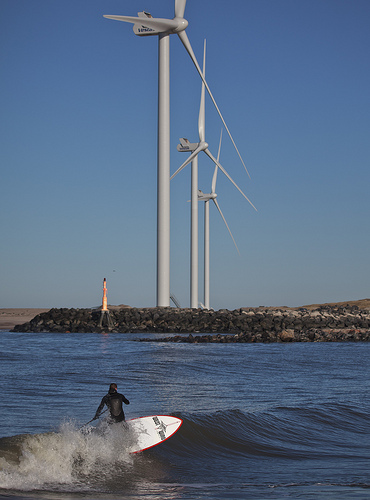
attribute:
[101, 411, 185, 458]
board — wide, white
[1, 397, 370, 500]
wave — foamy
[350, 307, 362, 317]
rock — large, black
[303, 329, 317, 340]
rock — large, black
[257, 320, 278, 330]
rock — large, black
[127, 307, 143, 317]
rock — large, black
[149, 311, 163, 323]
rock — large, black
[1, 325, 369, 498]
water — splashing, white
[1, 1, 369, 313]
sky — clear, cloudless, shades of blue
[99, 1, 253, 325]
wind turbine — tall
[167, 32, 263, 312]
wind turbine — tall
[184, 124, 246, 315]
wind turbine — tall